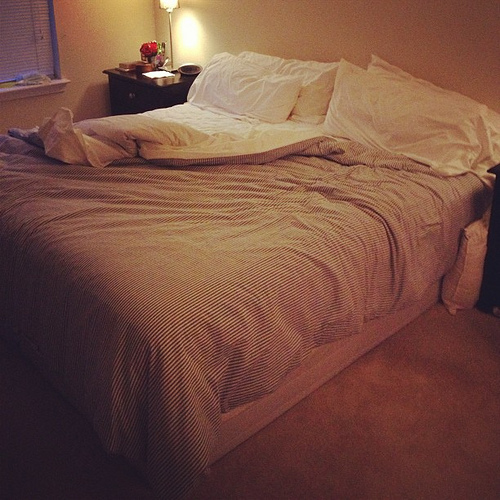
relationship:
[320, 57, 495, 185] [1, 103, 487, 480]
white pillow on bed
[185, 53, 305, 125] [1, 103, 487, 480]
pillow on bed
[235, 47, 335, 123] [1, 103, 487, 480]
pillow on bed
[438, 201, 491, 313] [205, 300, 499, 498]
pillow on floor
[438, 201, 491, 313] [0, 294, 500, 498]
pillow on floor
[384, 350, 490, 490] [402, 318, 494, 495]
carpet on floor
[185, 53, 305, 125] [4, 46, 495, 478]
pillow laying on bed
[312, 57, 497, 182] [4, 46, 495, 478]
pillow laying on bed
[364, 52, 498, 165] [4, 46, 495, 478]
pillow laying on bed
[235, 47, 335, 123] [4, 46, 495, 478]
pillow laying on bed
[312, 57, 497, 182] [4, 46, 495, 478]
pillow on bed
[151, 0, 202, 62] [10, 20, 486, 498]
light in bedroom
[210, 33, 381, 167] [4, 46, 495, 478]
pillows on bed